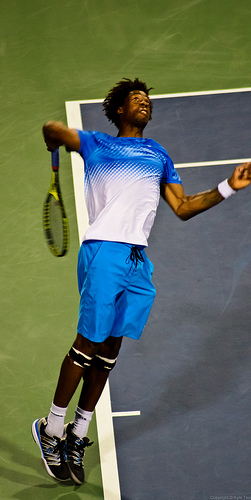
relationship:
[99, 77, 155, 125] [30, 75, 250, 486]
hair of he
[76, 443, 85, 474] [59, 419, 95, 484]
lace on shoe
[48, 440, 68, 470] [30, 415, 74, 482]
lace on shoe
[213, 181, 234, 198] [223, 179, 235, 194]
sweatband on wrist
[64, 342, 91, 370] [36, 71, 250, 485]
knee supports tennis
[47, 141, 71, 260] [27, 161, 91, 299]
tennis racket in middle of swing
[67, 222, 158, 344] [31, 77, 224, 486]
shorts are on tennis player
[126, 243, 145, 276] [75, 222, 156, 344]
string on shorts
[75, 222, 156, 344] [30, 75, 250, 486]
shorts are on he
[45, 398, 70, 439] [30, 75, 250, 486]
white sock on he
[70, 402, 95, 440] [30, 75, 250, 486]
white sock on he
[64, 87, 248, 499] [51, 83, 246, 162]
play area on court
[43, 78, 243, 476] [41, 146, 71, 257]
he holding racket